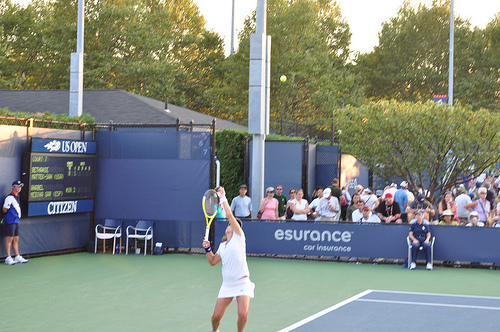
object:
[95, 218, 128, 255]
chairs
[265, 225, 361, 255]
advertisement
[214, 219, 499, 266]
partition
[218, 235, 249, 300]
white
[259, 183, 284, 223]
woman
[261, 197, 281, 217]
top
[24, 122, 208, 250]
fence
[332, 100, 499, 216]
tree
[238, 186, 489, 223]
spectators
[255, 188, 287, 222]
people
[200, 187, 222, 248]
racquet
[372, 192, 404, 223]
man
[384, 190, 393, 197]
hat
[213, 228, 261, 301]
outfit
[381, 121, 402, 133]
leaves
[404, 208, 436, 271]
referee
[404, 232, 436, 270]
chair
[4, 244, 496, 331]
tennis match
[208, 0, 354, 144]
trees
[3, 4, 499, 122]
background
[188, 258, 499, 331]
court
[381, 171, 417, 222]
audience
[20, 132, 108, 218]
scoreboard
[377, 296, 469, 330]
game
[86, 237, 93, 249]
corner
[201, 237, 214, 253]
hand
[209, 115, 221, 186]
pole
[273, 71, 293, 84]
tennis ball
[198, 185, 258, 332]
woman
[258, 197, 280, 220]
shirt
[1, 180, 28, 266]
ballboy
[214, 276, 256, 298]
skirt